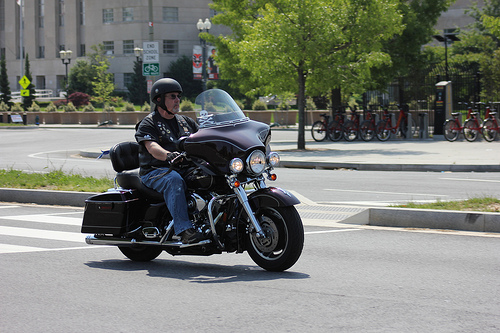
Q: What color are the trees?
A: Green.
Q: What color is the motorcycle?
A: Black.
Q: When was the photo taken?
A: Daytime.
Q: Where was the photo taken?
A: On the street.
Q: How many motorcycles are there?
A: One.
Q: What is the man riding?
A: Motorcycle.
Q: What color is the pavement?
A: Gray.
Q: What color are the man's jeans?
A: Blue.